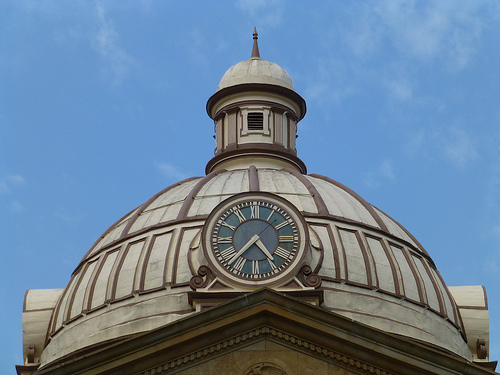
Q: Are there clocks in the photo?
A: Yes, there is a clock.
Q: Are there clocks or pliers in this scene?
A: Yes, there is a clock.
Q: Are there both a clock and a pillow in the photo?
A: No, there is a clock but no pillows.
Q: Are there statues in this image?
A: No, there are no statues.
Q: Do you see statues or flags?
A: No, there are no statues or flags.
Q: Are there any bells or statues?
A: No, there are no statues or bells.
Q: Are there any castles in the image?
A: No, there are no castles.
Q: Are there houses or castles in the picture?
A: No, there are no castles or houses.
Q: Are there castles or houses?
A: No, there are no castles or houses.